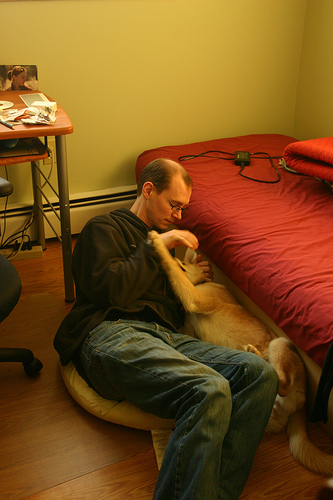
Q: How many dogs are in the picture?
A: One.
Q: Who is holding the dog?
A: A man.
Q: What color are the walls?
A: Beige.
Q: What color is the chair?
A: Black.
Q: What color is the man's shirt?
A: Black.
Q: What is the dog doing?
A: Playing with the man.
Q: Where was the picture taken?
A: In a bedroom.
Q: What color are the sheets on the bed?
A: Red.